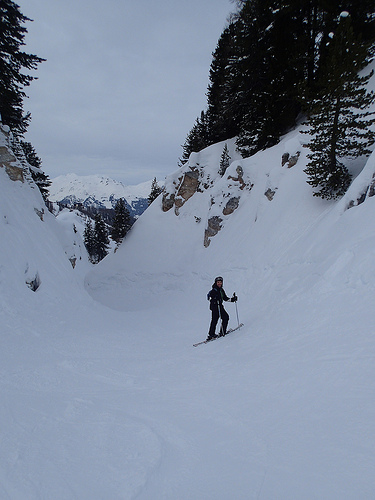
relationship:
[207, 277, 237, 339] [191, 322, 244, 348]
person standing on skis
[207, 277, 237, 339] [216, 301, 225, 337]
person holding ski pole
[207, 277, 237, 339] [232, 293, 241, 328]
person holding ski pole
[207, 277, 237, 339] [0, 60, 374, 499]
person standing in snow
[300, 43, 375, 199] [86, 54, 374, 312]
evergreen tree on side of hill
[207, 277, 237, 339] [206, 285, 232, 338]
person wearing clothing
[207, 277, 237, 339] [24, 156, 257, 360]
person standing in gulley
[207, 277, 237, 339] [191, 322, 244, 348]
person walking on skis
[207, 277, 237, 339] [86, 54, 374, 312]
person on hill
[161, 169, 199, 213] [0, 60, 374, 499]
rock sticking out of snow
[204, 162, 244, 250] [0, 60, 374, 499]
rock sticking out of snow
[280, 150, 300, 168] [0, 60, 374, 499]
rock sticking out of snow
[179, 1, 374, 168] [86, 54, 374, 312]
pine trees on side of hill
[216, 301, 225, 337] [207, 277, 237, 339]
ski pole of person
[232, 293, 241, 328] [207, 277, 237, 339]
ski pole of person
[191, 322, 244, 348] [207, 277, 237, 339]
skis of person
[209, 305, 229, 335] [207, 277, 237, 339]
snow pants of person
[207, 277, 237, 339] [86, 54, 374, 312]
person skiing on hill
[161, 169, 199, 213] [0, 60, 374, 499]
rock jutting out of snow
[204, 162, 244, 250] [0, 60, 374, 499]
rock jutting out of snow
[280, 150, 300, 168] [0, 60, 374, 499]
rock jutting out of snow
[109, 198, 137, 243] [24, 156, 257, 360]
evergreen tree growing in gulley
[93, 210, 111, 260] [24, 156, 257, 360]
evergreen tree growing in gulley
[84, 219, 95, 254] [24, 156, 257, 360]
evergreen tree growing in gulley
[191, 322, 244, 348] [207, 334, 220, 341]
skis attached to foot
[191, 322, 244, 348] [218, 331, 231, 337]
skis attached to foot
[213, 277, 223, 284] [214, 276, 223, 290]
hat warming head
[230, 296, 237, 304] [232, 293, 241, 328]
hand grasping ski pole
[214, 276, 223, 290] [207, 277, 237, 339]
head of person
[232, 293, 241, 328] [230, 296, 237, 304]
ski pole held in hand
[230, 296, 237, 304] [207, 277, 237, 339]
hand of person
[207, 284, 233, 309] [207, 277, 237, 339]
coat worn on person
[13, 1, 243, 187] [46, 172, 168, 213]
sky over mountains